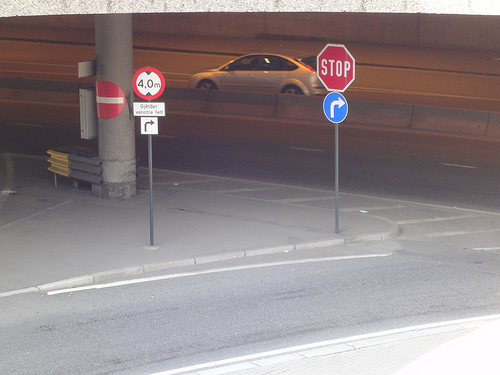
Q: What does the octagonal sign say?
A: Stop.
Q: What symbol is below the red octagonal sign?
A: Arrow.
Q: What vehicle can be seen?
A: Automobile.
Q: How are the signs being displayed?
A: On poles.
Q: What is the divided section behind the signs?
A: Roadway.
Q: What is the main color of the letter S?
A: White.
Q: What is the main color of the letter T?
A: White.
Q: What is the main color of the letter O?
A: White.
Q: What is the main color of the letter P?
A: White.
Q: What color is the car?
A: White.